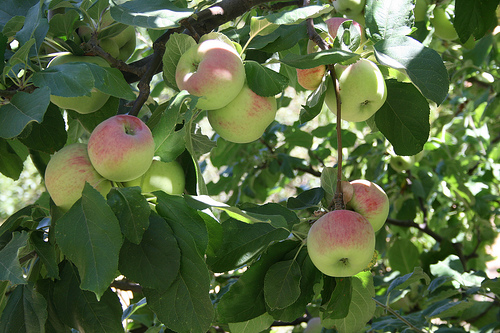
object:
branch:
[0, 219, 184, 333]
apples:
[300, 208, 382, 280]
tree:
[0, 0, 500, 333]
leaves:
[0, 82, 61, 141]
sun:
[198, 152, 221, 184]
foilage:
[105, 205, 226, 295]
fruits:
[314, 51, 393, 122]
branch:
[0, 0, 150, 96]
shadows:
[0, 186, 221, 333]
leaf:
[149, 189, 210, 261]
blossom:
[245, 15, 306, 76]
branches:
[275, 199, 499, 333]